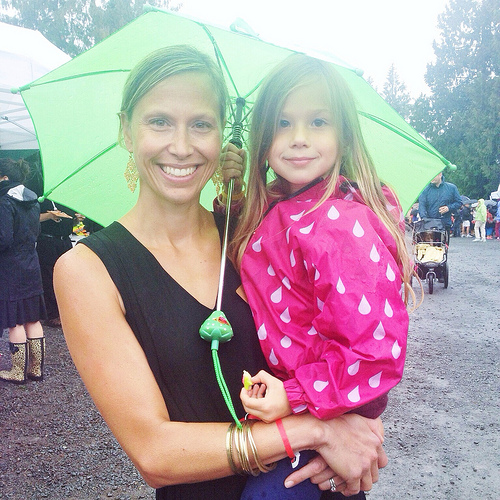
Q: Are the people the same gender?
A: No, they are both male and female.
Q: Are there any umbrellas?
A: Yes, there is an umbrella.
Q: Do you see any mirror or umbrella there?
A: Yes, there is an umbrella.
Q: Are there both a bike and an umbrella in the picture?
A: No, there is an umbrella but no bikes.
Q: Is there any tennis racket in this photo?
A: No, there are no rackets.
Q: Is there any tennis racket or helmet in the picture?
A: No, there are no rackets or helmets.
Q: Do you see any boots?
A: Yes, there are boots.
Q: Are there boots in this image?
A: Yes, there are boots.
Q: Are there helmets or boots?
A: Yes, there are boots.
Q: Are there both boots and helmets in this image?
A: No, there are boots but no helmets.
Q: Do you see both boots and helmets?
A: No, there are boots but no helmets.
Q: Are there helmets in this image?
A: No, there are no helmets.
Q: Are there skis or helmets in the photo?
A: No, there are no helmets or skis.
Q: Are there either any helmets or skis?
A: No, there are no helmets or skis.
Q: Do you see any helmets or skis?
A: No, there are no helmets or skis.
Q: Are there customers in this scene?
A: No, there are no customers.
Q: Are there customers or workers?
A: No, there are no customers or workers.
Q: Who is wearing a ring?
A: The girl is wearing a ring.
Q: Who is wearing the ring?
A: The girl is wearing a ring.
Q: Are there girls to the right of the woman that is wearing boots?
A: Yes, there is a girl to the right of the woman.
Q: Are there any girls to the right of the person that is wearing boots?
A: Yes, there is a girl to the right of the woman.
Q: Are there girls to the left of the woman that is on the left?
A: No, the girl is to the right of the woman.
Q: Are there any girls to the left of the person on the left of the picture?
A: No, the girl is to the right of the woman.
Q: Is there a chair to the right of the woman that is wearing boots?
A: No, there is a girl to the right of the woman.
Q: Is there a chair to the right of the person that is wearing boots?
A: No, there is a girl to the right of the woman.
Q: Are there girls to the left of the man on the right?
A: Yes, there is a girl to the left of the man.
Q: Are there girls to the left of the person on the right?
A: Yes, there is a girl to the left of the man.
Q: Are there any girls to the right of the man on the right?
A: No, the girl is to the left of the man.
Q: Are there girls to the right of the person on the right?
A: No, the girl is to the left of the man.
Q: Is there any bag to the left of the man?
A: No, there is a girl to the left of the man.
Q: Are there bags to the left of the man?
A: No, there is a girl to the left of the man.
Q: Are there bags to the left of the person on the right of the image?
A: No, there is a girl to the left of the man.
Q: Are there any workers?
A: No, there are no workers.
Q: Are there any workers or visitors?
A: No, there are no workers or visitors.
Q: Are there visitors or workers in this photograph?
A: No, there are no workers or visitors.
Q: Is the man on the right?
A: Yes, the man is on the right of the image.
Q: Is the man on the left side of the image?
A: No, the man is on the right of the image.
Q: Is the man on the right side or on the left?
A: The man is on the right of the image.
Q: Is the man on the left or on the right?
A: The man is on the right of the image.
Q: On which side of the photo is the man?
A: The man is on the right of the image.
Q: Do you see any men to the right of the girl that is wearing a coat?
A: Yes, there is a man to the right of the girl.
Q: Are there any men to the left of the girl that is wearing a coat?
A: No, the man is to the right of the girl.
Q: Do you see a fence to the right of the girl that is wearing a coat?
A: No, there is a man to the right of the girl.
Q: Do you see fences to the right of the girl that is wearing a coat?
A: No, there is a man to the right of the girl.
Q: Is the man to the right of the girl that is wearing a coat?
A: Yes, the man is to the right of the girl.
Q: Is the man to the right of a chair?
A: No, the man is to the right of the girl.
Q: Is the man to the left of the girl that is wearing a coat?
A: No, the man is to the right of the girl.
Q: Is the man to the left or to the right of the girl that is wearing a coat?
A: The man is to the right of the girl.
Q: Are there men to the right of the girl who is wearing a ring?
A: Yes, there is a man to the right of the girl.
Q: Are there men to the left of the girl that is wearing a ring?
A: No, the man is to the right of the girl.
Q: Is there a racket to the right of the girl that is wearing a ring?
A: No, there is a man to the right of the girl.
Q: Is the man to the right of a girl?
A: Yes, the man is to the right of a girl.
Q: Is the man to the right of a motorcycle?
A: No, the man is to the right of a girl.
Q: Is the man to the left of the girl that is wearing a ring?
A: No, the man is to the right of the girl.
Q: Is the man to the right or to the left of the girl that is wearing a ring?
A: The man is to the right of the girl.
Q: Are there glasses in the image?
A: No, there are no glasses.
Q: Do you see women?
A: Yes, there is a woman.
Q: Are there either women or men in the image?
A: Yes, there is a woman.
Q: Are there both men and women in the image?
A: Yes, there are both a woman and a man.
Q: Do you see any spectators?
A: No, there are no spectators.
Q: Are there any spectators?
A: No, there are no spectators.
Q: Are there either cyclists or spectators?
A: No, there are no spectators or cyclists.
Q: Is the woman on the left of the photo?
A: Yes, the woman is on the left of the image.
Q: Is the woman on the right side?
A: No, the woman is on the left of the image.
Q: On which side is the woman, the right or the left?
A: The woman is on the left of the image.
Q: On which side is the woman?
A: The woman is on the left of the image.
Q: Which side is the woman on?
A: The woman is on the left of the image.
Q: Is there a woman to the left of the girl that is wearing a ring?
A: Yes, there is a woman to the left of the girl.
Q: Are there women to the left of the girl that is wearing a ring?
A: Yes, there is a woman to the left of the girl.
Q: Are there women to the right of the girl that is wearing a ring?
A: No, the woman is to the left of the girl.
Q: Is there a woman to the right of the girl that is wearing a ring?
A: No, the woman is to the left of the girl.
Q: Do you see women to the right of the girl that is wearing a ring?
A: No, the woman is to the left of the girl.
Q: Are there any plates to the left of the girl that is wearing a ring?
A: No, there is a woman to the left of the girl.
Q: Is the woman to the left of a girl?
A: Yes, the woman is to the left of a girl.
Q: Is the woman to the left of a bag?
A: No, the woman is to the left of a girl.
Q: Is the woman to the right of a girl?
A: No, the woman is to the left of a girl.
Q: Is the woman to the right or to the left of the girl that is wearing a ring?
A: The woman is to the left of the girl.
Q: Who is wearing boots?
A: The woman is wearing boots.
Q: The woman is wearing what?
A: The woman is wearing boots.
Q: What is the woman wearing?
A: The woman is wearing boots.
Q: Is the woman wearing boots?
A: Yes, the woman is wearing boots.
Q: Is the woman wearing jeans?
A: No, the woman is wearing boots.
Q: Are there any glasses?
A: No, there are no glasses.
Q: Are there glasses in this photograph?
A: No, there are no glasses.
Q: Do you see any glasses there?
A: No, there are no glasses.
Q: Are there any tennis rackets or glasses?
A: No, there are no glasses or tennis rackets.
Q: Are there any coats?
A: Yes, there is a coat.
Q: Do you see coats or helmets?
A: Yes, there is a coat.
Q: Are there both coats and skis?
A: No, there is a coat but no skis.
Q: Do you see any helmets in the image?
A: No, there are no helmets.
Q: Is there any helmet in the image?
A: No, there are no helmets.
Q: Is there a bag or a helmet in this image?
A: No, there are no helmets or bags.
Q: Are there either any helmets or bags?
A: No, there are no helmets or bags.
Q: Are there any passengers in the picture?
A: No, there are no passengers.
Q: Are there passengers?
A: No, there are no passengers.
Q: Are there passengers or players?
A: No, there are no passengers or players.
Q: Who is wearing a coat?
A: The girl is wearing a coat.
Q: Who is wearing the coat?
A: The girl is wearing a coat.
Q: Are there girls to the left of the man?
A: Yes, there is a girl to the left of the man.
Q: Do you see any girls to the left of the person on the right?
A: Yes, there is a girl to the left of the man.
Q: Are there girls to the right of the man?
A: No, the girl is to the left of the man.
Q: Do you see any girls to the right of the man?
A: No, the girl is to the left of the man.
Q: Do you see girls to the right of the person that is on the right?
A: No, the girl is to the left of the man.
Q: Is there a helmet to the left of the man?
A: No, there is a girl to the left of the man.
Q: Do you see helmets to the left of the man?
A: No, there is a girl to the left of the man.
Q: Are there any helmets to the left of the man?
A: No, there is a girl to the left of the man.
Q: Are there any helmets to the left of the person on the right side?
A: No, there is a girl to the left of the man.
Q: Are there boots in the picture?
A: Yes, there are boots.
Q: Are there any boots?
A: Yes, there are boots.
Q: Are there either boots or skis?
A: Yes, there are boots.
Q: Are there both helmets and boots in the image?
A: No, there are boots but no helmets.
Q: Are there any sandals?
A: No, there are no sandals.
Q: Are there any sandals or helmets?
A: No, there are no sandals or helmets.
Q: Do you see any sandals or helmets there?
A: No, there are no sandals or helmets.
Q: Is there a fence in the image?
A: No, there are no fences.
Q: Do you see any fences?
A: No, there are no fences.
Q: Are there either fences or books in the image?
A: No, there are no fences or books.